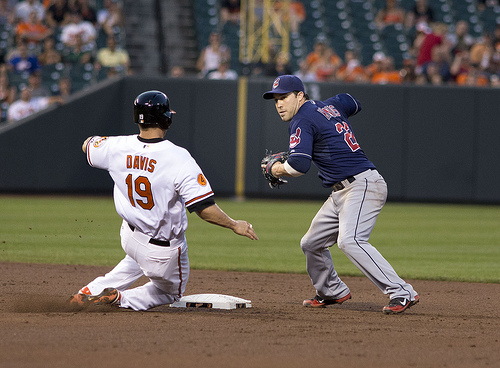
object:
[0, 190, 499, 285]
grass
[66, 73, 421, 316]
action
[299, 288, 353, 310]
shoe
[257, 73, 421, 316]
baseball player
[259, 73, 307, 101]
cap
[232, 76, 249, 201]
pole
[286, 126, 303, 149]
logo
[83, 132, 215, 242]
jersey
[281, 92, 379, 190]
jersey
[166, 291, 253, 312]
white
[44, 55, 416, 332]
baseball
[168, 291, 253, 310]
base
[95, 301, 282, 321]
shadow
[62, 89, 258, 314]
baseball player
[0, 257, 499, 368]
infield dirt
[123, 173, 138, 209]
number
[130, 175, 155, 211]
number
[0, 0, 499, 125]
spectators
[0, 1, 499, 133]
stands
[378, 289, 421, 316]
shoe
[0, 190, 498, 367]
field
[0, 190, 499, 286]
outfield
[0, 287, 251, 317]
second base